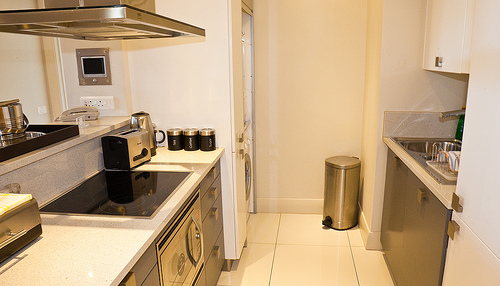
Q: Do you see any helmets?
A: No, there are no helmets.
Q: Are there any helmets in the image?
A: No, there are no helmets.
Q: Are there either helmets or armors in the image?
A: No, there are no helmets or armors.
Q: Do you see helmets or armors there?
A: No, there are no helmets or armors.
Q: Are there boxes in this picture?
A: No, there are no boxes.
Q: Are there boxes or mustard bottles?
A: No, there are no boxes or mustard bottles.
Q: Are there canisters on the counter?
A: Yes, there is a canister on the counter.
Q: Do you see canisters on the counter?
A: Yes, there is a canister on the counter.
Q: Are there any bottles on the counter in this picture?
A: No, there is a canister on the counter.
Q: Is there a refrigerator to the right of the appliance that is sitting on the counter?
A: No, there is a canister to the right of the toaster.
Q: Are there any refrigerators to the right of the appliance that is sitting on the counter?
A: No, there is a canister to the right of the toaster.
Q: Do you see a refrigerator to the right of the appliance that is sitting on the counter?
A: No, there is a canister to the right of the toaster.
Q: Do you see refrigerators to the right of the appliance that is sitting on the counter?
A: No, there is a canister to the right of the toaster.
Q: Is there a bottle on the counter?
A: No, there is a canister on the counter.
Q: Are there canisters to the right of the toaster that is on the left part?
A: Yes, there is a canister to the right of the toaster.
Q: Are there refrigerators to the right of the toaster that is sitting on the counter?
A: No, there is a canister to the right of the toaster.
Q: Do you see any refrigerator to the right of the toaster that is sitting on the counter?
A: No, there is a canister to the right of the toaster.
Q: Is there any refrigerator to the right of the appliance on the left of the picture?
A: No, there is a canister to the right of the toaster.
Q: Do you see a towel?
A: No, there are no towels.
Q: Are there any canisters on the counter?
A: Yes, there is a canister on the counter.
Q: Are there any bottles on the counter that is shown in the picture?
A: No, there is a canister on the counter.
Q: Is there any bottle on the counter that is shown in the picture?
A: No, there is a canister on the counter.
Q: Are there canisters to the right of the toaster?
A: Yes, there is a canister to the right of the toaster.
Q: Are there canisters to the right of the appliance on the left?
A: Yes, there is a canister to the right of the toaster.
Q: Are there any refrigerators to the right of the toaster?
A: No, there is a canister to the right of the toaster.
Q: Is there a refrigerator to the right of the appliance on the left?
A: No, there is a canister to the right of the toaster.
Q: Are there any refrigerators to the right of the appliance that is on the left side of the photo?
A: No, there is a canister to the right of the toaster.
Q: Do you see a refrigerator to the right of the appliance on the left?
A: No, there is a canister to the right of the toaster.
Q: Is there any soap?
A: No, there are no soaps.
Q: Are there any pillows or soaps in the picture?
A: No, there are no soaps or pillows.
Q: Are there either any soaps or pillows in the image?
A: No, there are no soaps or pillows.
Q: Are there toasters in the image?
A: Yes, there is a toaster.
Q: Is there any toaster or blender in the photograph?
A: Yes, there is a toaster.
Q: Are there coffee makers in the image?
A: No, there are no coffee makers.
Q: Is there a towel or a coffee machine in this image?
A: No, there are no coffee makers or towels.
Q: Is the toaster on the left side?
A: Yes, the toaster is on the left of the image.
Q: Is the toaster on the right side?
A: No, the toaster is on the left of the image.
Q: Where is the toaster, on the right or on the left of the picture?
A: The toaster is on the left of the image.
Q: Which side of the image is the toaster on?
A: The toaster is on the left of the image.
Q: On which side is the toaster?
A: The toaster is on the left of the image.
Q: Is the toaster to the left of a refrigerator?
A: No, the toaster is to the left of the canister.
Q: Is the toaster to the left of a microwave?
A: No, the toaster is to the left of the canister.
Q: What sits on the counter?
A: The toaster sits on the counter.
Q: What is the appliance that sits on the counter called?
A: The appliance is a toaster.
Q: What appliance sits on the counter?
A: The appliance is a toaster.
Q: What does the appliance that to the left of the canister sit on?
A: The toaster sits on the counter.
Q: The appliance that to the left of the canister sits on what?
A: The toaster sits on the counter.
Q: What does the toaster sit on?
A: The toaster sits on the counter.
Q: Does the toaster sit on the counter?
A: Yes, the toaster sits on the counter.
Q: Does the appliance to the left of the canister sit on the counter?
A: Yes, the toaster sits on the counter.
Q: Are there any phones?
A: Yes, there is a phone.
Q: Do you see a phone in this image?
A: Yes, there is a phone.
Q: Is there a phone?
A: Yes, there is a phone.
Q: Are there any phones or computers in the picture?
A: Yes, there is a phone.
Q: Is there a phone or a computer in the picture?
A: Yes, there is a phone.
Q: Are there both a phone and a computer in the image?
A: No, there is a phone but no computers.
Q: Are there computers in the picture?
A: No, there are no computers.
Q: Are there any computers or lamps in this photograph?
A: No, there are no computers or lamps.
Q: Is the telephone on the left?
A: Yes, the telephone is on the left of the image.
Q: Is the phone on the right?
A: No, the phone is on the left of the image.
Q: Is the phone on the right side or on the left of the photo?
A: The phone is on the left of the image.